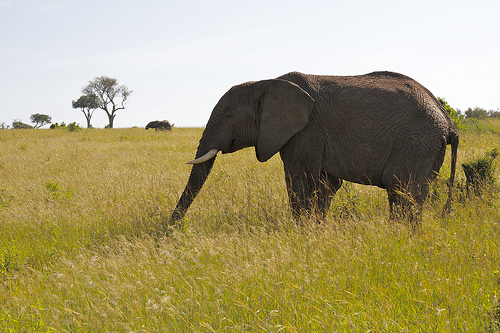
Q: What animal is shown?
A: Elephant.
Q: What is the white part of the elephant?
A: Tusk.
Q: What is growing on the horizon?
A: Tree.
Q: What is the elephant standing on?
A: Grass.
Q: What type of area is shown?
A: Savanah.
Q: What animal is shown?
A: Elephant.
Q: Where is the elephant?
A: In a field.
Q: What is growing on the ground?
A: Grass.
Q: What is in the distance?
A: A tree.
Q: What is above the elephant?
A: The clear blue sky.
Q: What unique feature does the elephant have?
A: A trunk.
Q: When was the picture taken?
A: Daytime.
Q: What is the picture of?
A: An elephant.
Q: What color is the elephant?
A: Brown.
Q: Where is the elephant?
A: An open field.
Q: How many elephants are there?
A: One.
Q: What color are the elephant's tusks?
A: White.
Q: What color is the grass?
A: Green and tan.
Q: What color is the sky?
A: Blue.